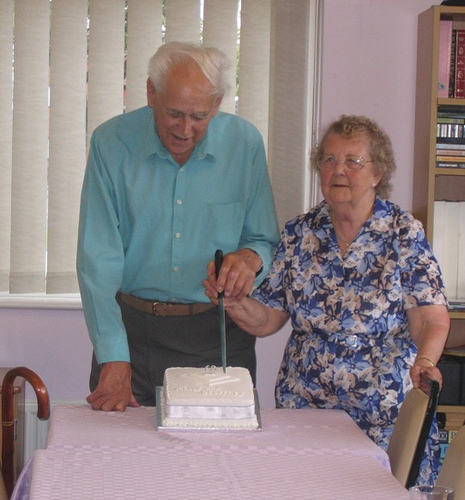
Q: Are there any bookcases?
A: Yes, there is a bookcase.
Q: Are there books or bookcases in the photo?
A: Yes, there is a bookcase.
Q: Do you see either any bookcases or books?
A: Yes, there is a bookcase.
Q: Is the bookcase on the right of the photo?
A: Yes, the bookcase is on the right of the image.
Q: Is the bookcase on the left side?
A: No, the bookcase is on the right of the image.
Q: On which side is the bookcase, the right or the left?
A: The bookcase is on the right of the image.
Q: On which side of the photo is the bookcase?
A: The bookcase is on the right of the image.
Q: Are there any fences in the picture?
A: No, there are no fences.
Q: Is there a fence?
A: No, there are no fences.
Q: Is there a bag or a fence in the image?
A: No, there are no fences or bags.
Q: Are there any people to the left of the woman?
A: Yes, there is a person to the left of the woman.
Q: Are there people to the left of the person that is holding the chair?
A: Yes, there is a person to the left of the woman.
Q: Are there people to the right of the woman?
A: No, the person is to the left of the woman.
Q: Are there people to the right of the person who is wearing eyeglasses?
A: No, the person is to the left of the woman.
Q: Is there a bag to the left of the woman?
A: No, there is a person to the left of the woman.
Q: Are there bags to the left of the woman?
A: No, there is a person to the left of the woman.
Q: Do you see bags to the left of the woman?
A: No, there is a person to the left of the woman.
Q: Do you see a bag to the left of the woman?
A: No, there is a person to the left of the woman.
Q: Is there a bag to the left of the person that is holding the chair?
A: No, there is a person to the left of the woman.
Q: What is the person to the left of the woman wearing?
A: The person is wearing a shirt.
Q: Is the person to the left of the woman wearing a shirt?
A: Yes, the person is wearing a shirt.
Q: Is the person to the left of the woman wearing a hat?
A: No, the person is wearing a shirt.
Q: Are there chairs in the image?
A: Yes, there is a chair.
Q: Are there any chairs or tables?
A: Yes, there is a chair.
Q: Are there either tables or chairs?
A: Yes, there is a chair.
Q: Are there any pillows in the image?
A: No, there are no pillows.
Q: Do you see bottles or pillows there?
A: No, there are no pillows or bottles.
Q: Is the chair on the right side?
A: Yes, the chair is on the right of the image.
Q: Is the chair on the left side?
A: No, the chair is on the right of the image.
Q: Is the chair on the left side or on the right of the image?
A: The chair is on the right of the image.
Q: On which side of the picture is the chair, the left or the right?
A: The chair is on the right of the image.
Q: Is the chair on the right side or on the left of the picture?
A: The chair is on the right of the image.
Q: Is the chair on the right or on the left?
A: The chair is on the right of the image.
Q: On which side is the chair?
A: The chair is on the right of the image.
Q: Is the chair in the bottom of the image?
A: Yes, the chair is in the bottom of the image.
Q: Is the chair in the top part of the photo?
A: No, the chair is in the bottom of the image.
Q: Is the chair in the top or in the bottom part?
A: The chair is in the bottom of the image.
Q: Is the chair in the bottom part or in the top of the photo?
A: The chair is in the bottom of the image.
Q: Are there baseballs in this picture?
A: No, there are no baseballs.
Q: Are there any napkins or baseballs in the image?
A: No, there are no baseballs or napkins.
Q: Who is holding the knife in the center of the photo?
A: The couple is holding the knife.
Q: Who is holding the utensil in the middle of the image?
A: The couple is holding the knife.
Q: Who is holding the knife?
A: The couple is holding the knife.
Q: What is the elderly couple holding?
A: The couple is holding the knife.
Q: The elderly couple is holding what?
A: The couple is holding the knife.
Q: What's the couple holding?
A: The couple is holding the knife.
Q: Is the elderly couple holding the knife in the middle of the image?
A: Yes, the couple is holding the knife.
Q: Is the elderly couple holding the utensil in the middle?
A: Yes, the couple is holding the knife.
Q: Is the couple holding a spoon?
A: No, the couple is holding the knife.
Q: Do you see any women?
A: Yes, there is a woman.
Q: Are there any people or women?
A: Yes, there is a woman.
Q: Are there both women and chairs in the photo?
A: Yes, there are both a woman and a chair.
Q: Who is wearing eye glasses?
A: The woman is wearing eye glasses.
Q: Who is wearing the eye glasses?
A: The woman is wearing eye glasses.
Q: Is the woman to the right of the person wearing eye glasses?
A: Yes, the woman is wearing eye glasses.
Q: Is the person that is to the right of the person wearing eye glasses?
A: Yes, the woman is wearing eye glasses.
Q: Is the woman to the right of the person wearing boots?
A: No, the woman is wearing eye glasses.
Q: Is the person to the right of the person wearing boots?
A: No, the woman is wearing eye glasses.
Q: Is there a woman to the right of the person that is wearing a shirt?
A: Yes, there is a woman to the right of the person.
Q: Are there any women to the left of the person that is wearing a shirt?
A: No, the woman is to the right of the person.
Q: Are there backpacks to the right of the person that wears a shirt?
A: No, there is a woman to the right of the person.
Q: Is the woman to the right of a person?
A: Yes, the woman is to the right of a person.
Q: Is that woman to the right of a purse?
A: No, the woman is to the right of a person.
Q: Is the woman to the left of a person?
A: No, the woman is to the right of a person.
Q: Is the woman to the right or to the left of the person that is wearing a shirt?
A: The woman is to the right of the person.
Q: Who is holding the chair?
A: The woman is holding the chair.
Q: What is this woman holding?
A: The woman is holding the chair.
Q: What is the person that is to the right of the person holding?
A: The woman is holding the chair.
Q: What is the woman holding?
A: The woman is holding the chair.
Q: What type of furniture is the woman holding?
A: The woman is holding the chair.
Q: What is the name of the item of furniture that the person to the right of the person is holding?
A: The piece of furniture is a chair.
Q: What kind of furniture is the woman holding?
A: The woman is holding the chair.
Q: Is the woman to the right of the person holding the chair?
A: Yes, the woman is holding the chair.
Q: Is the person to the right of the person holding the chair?
A: Yes, the woman is holding the chair.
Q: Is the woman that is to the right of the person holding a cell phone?
A: No, the woman is holding the chair.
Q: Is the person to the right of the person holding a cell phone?
A: No, the woman is holding the chair.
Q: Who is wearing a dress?
A: The woman is wearing a dress.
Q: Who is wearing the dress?
A: The woman is wearing a dress.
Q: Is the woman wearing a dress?
A: Yes, the woman is wearing a dress.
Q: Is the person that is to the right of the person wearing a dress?
A: Yes, the woman is wearing a dress.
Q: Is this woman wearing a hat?
A: No, the woman is wearing a dress.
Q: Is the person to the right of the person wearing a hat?
A: No, the woman is wearing a dress.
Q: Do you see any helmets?
A: No, there are no helmets.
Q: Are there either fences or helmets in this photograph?
A: No, there are no helmets or fences.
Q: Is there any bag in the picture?
A: No, there are no bags.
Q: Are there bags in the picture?
A: No, there are no bags.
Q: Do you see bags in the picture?
A: No, there are no bags.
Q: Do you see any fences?
A: No, there are no fences.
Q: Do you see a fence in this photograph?
A: No, there are no fences.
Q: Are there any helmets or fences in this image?
A: No, there are no fences or helmets.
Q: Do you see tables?
A: Yes, there is a table.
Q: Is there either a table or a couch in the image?
A: Yes, there is a table.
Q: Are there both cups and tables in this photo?
A: No, there is a table but no cups.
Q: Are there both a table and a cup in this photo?
A: No, there is a table but no cups.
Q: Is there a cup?
A: No, there are no cups.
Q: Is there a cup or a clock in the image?
A: No, there are no cups or clocks.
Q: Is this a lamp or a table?
A: This is a table.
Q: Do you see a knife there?
A: Yes, there is a knife.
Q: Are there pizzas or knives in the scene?
A: Yes, there is a knife.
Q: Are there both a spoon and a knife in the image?
A: No, there is a knife but no spoons.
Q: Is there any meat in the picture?
A: No, there is no meat.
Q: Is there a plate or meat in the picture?
A: No, there are no meat or plates.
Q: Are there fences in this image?
A: No, there are no fences.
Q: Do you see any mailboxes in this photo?
A: No, there are no mailboxes.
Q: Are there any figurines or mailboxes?
A: No, there are no mailboxes or figurines.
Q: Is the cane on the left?
A: Yes, the cane is on the left of the image.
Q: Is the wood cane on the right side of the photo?
A: No, the cane is on the left of the image.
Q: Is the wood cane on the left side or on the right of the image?
A: The cane is on the left of the image.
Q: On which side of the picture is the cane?
A: The cane is on the left of the image.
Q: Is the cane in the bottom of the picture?
A: Yes, the cane is in the bottom of the image.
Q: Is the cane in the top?
A: No, the cane is in the bottom of the image.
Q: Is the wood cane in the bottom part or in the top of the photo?
A: The cane is in the bottom of the image.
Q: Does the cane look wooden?
A: Yes, the cane is wooden.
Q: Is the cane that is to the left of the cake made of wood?
A: Yes, the cane is made of wood.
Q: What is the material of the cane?
A: The cane is made of wood.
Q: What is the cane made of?
A: The cane is made of wood.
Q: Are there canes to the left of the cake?
A: Yes, there is a cane to the left of the cake.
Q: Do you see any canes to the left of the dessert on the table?
A: Yes, there is a cane to the left of the cake.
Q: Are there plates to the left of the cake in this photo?
A: No, there is a cane to the left of the cake.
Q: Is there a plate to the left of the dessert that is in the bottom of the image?
A: No, there is a cane to the left of the cake.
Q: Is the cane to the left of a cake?
A: Yes, the cane is to the left of a cake.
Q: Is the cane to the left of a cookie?
A: No, the cane is to the left of a cake.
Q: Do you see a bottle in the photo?
A: No, there are no bottles.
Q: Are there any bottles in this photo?
A: No, there are no bottles.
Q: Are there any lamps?
A: No, there are no lamps.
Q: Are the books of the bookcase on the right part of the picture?
A: Yes, the books are on the right of the image.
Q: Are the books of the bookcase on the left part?
A: No, the books are on the right of the image.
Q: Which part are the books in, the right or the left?
A: The books are on the right of the image.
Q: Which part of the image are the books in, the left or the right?
A: The books are on the right of the image.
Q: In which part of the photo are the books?
A: The books are on the right of the image.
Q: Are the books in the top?
A: Yes, the books are in the top of the image.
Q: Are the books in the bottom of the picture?
A: No, the books are in the top of the image.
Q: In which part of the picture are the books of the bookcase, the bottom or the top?
A: The books are in the top of the image.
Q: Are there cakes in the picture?
A: Yes, there is a cake.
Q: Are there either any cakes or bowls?
A: Yes, there is a cake.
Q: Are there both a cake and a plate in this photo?
A: No, there is a cake but no plates.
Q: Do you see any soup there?
A: No, there is no soup.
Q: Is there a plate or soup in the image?
A: No, there are no soup or plates.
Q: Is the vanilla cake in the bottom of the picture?
A: Yes, the cake is in the bottom of the image.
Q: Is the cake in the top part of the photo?
A: No, the cake is in the bottom of the image.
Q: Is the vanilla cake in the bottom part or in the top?
A: The cake is in the bottom of the image.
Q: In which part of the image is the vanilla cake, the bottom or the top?
A: The cake is in the bottom of the image.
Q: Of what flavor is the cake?
A: This is a vanilla cake.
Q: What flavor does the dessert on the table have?
A: This is a vanilla cake.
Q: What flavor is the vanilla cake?
A: This is a vanilla cake.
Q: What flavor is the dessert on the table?
A: This is a vanilla cake.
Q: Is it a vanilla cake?
A: Yes, this is a vanilla cake.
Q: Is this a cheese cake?
A: No, this is a vanilla cake.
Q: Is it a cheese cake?
A: No, this is a vanilla cake.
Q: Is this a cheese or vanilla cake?
A: This is a vanilla cake.